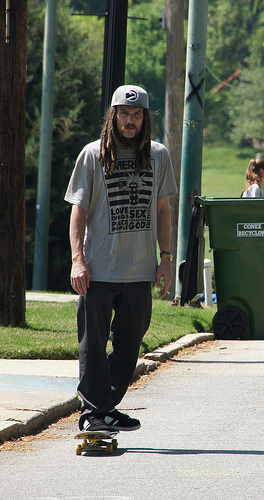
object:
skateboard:
[74, 428, 117, 456]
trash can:
[178, 194, 263, 339]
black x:
[185, 69, 207, 110]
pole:
[174, 0, 208, 299]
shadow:
[84, 443, 264, 458]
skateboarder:
[64, 82, 178, 433]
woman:
[241, 154, 264, 198]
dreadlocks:
[97, 105, 153, 176]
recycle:
[237, 225, 263, 238]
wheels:
[75, 444, 82, 456]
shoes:
[83, 412, 112, 429]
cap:
[110, 84, 149, 107]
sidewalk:
[0, 357, 79, 440]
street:
[0, 340, 264, 500]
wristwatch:
[158, 250, 175, 263]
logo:
[124, 89, 139, 104]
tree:
[25, 0, 263, 285]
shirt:
[63, 139, 179, 285]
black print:
[99, 151, 153, 233]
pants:
[76, 283, 152, 428]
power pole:
[1, 1, 26, 328]